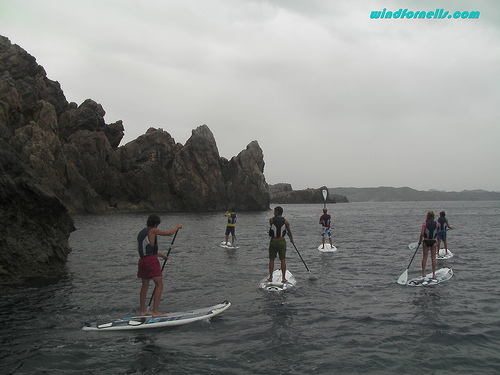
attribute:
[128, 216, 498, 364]
paddleboards — white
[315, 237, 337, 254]
paddleboard — white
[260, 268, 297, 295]
paddleboard — white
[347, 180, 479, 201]
mountains — hazy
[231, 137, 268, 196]
cliff — rock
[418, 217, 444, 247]
shirt — pink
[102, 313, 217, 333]
edge — white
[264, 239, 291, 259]
swim trunks — gren